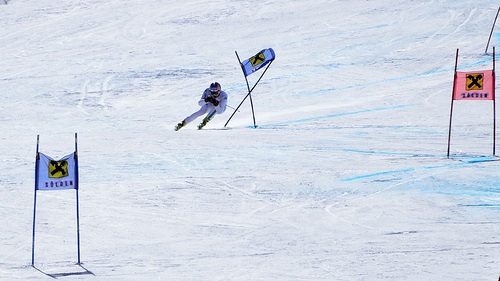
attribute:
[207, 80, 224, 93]
helmet — plastic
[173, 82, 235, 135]
skier — at angle, wearing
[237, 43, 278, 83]
flag — blue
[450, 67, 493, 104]
flag — pink, boundary, red, stuck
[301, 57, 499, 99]
line — blue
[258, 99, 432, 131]
line — blue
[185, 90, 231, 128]
outfit — on, blue, white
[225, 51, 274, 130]
poles — blue